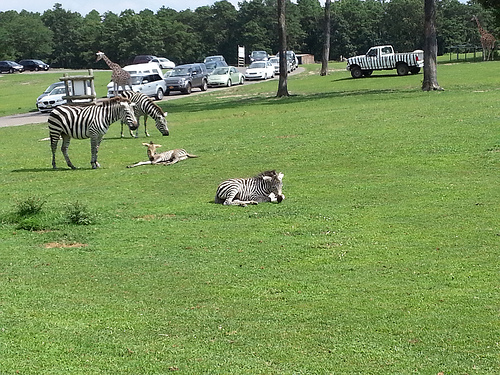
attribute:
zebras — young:
[22, 88, 289, 210]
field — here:
[1, 69, 497, 372]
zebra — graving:
[120, 96, 177, 137]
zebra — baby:
[204, 168, 293, 208]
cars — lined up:
[38, 44, 302, 119]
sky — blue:
[5, 1, 248, 12]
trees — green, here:
[4, 8, 499, 73]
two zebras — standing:
[40, 86, 176, 171]